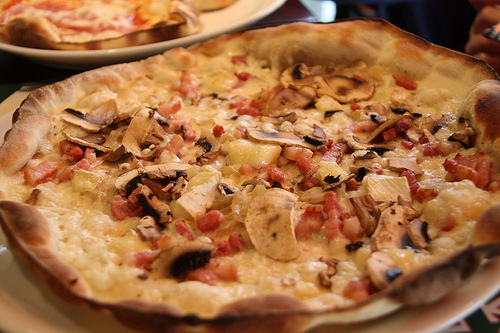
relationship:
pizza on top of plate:
[32, 70, 487, 292] [4, 7, 499, 332]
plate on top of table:
[4, 6, 296, 64] [0, 55, 69, 115]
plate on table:
[4, 7, 499, 332] [0, 55, 69, 115]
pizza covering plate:
[32, 70, 487, 292] [4, 7, 499, 332]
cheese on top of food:
[157, 60, 262, 111] [32, 70, 487, 292]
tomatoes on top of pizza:
[247, 156, 363, 246] [32, 70, 487, 292]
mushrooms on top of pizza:
[72, 109, 118, 153] [32, 70, 487, 292]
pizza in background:
[8, 4, 221, 49] [12, 2, 496, 68]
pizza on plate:
[32, 70, 487, 292] [4, 7, 499, 332]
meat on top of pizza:
[131, 172, 195, 198] [32, 70, 487, 292]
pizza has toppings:
[32, 70, 487, 292] [123, 122, 437, 233]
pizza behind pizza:
[32, 70, 487, 292] [8, 4, 221, 49]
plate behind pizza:
[4, 6, 296, 64] [32, 70, 487, 292]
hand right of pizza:
[461, 12, 499, 66] [32, 70, 487, 292]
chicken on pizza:
[359, 174, 413, 206] [32, 70, 487, 292]